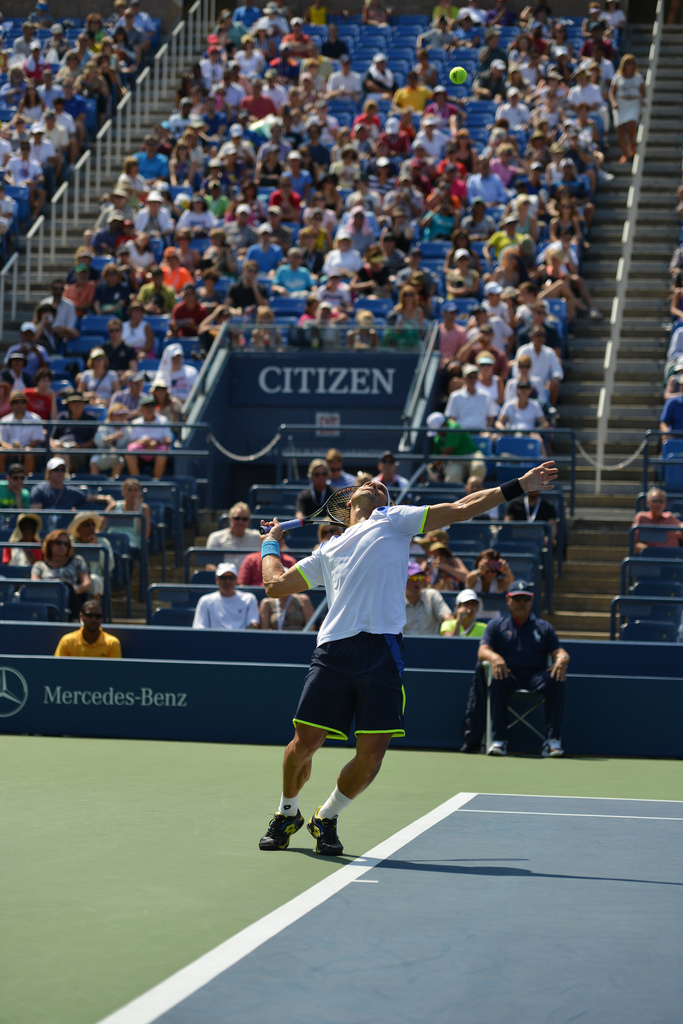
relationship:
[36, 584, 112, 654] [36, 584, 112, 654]
person wearing a shirt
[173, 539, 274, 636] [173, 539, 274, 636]
person wearing a shirt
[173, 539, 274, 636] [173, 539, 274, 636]
person wearing a cap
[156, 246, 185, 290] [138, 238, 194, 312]
person wearing shirt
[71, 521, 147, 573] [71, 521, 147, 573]
person wearing shirt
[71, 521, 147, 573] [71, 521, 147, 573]
person wearing hat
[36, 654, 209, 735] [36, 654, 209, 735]
advertisement on wall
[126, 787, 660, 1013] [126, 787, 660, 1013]
line on court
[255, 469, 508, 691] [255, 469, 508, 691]
man wearing shirt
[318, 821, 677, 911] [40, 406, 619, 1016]
shadow on court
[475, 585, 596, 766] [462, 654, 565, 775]
man in chair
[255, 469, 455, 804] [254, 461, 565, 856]
man swinging racquet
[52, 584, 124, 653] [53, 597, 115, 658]
person wearing shirt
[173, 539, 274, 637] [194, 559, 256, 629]
person wearing shirt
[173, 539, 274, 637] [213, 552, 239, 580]
person wearing hat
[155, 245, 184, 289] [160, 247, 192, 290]
person wearing shirt